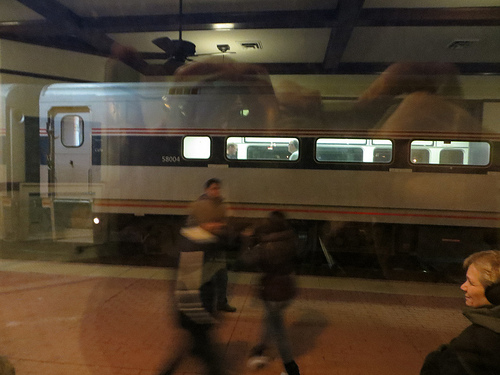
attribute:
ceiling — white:
[1, 0, 499, 75]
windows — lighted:
[170, 115, 499, 187]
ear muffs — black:
[480, 276, 497, 305]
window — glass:
[6, 5, 493, 372]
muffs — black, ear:
[485, 280, 498, 306]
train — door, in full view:
[30, 68, 497, 268]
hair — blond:
[462, 246, 497, 297]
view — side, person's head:
[438, 240, 494, 337]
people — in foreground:
[164, 175, 309, 373]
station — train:
[4, 4, 497, 364]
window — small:
[409, 137, 491, 169]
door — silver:
[39, 104, 111, 193]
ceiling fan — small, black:
[130, 45, 235, 65]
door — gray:
[44, 105, 101, 206]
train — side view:
[56, 64, 492, 229]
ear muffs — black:
[485, 280, 498, 306]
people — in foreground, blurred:
[173, 176, 300, 373]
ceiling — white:
[102, 19, 363, 72]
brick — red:
[94, 265, 202, 316]